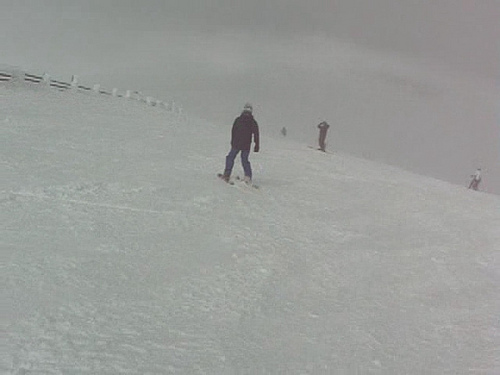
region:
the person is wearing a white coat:
[470, 165, 487, 185]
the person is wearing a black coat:
[223, 113, 264, 148]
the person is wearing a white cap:
[241, 96, 254, 114]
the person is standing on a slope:
[213, 87, 270, 202]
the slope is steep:
[70, 112, 192, 310]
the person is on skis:
[213, 166, 261, 193]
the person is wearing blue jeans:
[221, 142, 256, 180]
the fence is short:
[34, 67, 151, 110]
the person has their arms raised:
[312, 103, 334, 158]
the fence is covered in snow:
[22, 65, 176, 119]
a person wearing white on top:
[466, 165, 485, 202]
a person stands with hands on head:
[311, 114, 334, 152]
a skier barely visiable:
[277, 123, 291, 138]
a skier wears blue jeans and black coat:
[214, 90, 274, 195]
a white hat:
[238, 97, 257, 117]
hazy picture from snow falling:
[51, 23, 497, 168]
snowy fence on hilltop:
[0, 58, 201, 115]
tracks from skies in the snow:
[17, 163, 235, 255]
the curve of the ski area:
[161, 73, 496, 232]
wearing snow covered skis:
[216, 165, 278, 195]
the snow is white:
[204, 269, 293, 371]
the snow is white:
[283, 294, 335, 366]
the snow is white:
[281, 232, 343, 359]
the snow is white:
[258, 270, 318, 372]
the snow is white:
[232, 277, 289, 353]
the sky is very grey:
[108, 20, 467, 150]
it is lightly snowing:
[57, 31, 426, 283]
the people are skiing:
[202, 93, 492, 210]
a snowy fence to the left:
[2, 63, 202, 120]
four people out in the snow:
[193, 107, 498, 218]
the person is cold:
[192, 91, 267, 202]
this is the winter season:
[35, 42, 436, 292]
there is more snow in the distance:
[132, 102, 493, 296]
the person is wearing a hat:
[227, 92, 258, 121]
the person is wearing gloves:
[210, 137, 271, 162]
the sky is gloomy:
[342, 22, 451, 145]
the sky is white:
[363, 32, 452, 142]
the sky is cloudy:
[350, 29, 458, 117]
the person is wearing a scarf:
[233, 112, 263, 123]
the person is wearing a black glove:
[252, 140, 260, 156]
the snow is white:
[220, 260, 392, 321]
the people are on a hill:
[211, 85, 351, 199]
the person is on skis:
[210, 95, 264, 192]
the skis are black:
[209, 162, 258, 194]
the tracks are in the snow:
[52, 162, 129, 214]